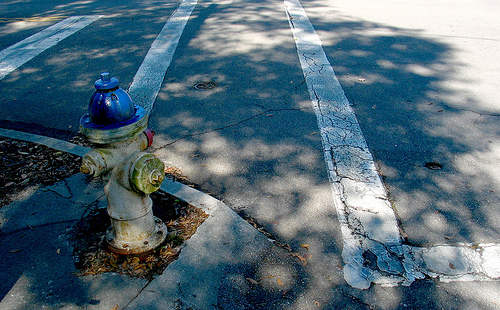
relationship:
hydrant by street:
[78, 71, 168, 256] [2, 1, 499, 282]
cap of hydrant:
[79, 74, 145, 130] [78, 71, 168, 256]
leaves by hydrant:
[97, 254, 147, 276] [78, 71, 168, 256]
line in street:
[284, 1, 401, 289] [2, 1, 499, 282]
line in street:
[1, 14, 102, 79] [2, 1, 499, 282]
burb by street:
[1, 128, 83, 156] [2, 1, 499, 282]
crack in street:
[150, 108, 304, 155] [2, 1, 499, 282]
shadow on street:
[317, 21, 492, 110] [2, 1, 499, 282]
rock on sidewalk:
[21, 173, 27, 179] [1, 216, 247, 310]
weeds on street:
[382, 175, 396, 209] [2, 1, 499, 282]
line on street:
[284, 1, 401, 289] [2, 1, 499, 282]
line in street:
[128, 1, 198, 112] [2, 1, 499, 282]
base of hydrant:
[104, 214, 167, 258] [78, 71, 168, 256]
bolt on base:
[144, 240, 149, 246] [104, 214, 167, 258]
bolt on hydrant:
[158, 229, 162, 235] [78, 71, 168, 256]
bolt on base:
[108, 237, 113, 244] [104, 214, 167, 258]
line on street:
[128, 1, 198, 112] [2, 1, 499, 282]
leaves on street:
[97, 254, 147, 276] [2, 1, 499, 282]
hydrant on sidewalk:
[78, 71, 168, 256] [1, 216, 247, 310]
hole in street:
[426, 160, 441, 170] [2, 1, 499, 282]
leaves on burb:
[27, 150, 65, 170] [1, 128, 83, 156]